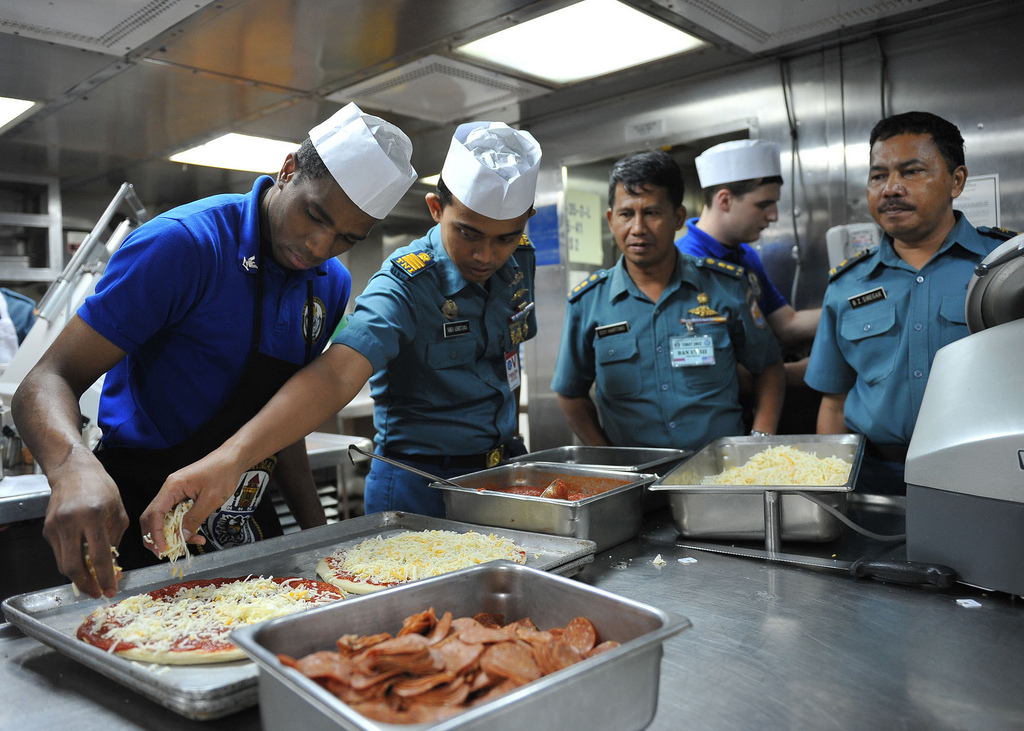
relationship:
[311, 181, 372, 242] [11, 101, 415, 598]
forehead of man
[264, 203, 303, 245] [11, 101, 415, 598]
cheek of man